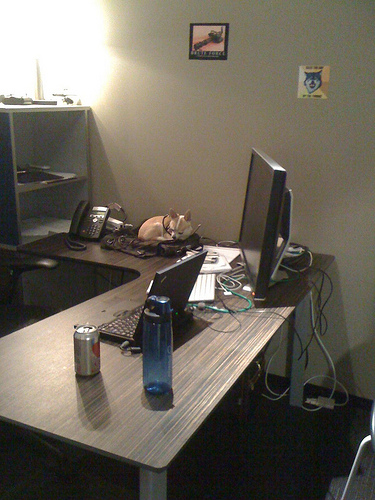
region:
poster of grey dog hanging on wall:
[295, 64, 330, 98]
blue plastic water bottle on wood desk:
[142, 296, 174, 396]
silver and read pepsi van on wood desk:
[74, 325, 98, 376]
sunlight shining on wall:
[40, 14, 80, 74]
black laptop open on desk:
[94, 250, 208, 336]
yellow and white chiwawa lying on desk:
[138, 208, 194, 242]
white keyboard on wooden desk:
[191, 272, 216, 302]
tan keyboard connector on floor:
[306, 396, 338, 408]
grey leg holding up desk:
[291, 294, 310, 406]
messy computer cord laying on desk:
[223, 267, 241, 314]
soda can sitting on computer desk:
[73, 324, 101, 374]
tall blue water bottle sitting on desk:
[142, 291, 173, 391]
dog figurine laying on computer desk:
[138, 209, 200, 242]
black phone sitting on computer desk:
[65, 202, 109, 251]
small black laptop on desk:
[96, 251, 209, 340]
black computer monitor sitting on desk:
[240, 146, 295, 299]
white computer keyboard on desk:
[190, 275, 217, 299]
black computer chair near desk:
[0, 257, 58, 335]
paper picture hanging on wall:
[188, 22, 228, 57]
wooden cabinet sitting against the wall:
[2, 107, 93, 307]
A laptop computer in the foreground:
[96, 242, 215, 348]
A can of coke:
[59, 312, 109, 384]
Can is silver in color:
[70, 317, 106, 384]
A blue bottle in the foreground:
[134, 287, 184, 409]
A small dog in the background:
[134, 205, 203, 248]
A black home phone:
[66, 196, 114, 257]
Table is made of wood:
[3, 221, 343, 467]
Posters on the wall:
[177, 10, 344, 121]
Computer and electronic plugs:
[268, 248, 354, 417]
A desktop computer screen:
[230, 141, 307, 315]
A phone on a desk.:
[61, 200, 110, 254]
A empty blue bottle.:
[139, 292, 175, 407]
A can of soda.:
[72, 321, 103, 381]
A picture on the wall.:
[297, 62, 331, 100]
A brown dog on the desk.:
[134, 206, 196, 244]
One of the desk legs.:
[136, 467, 168, 499]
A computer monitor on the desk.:
[233, 145, 293, 302]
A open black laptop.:
[92, 250, 212, 345]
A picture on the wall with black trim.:
[188, 20, 229, 61]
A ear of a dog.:
[166, 204, 177, 222]